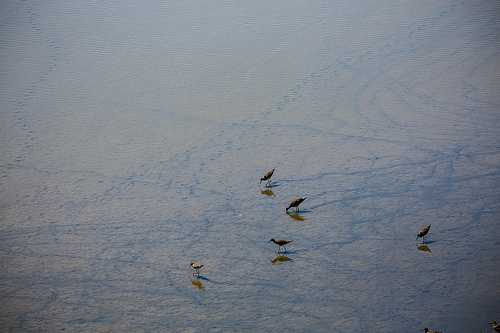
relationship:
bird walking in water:
[259, 168, 276, 186] [16, 102, 468, 301]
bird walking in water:
[284, 194, 319, 216] [16, 102, 468, 301]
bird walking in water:
[414, 224, 432, 241] [16, 102, 468, 301]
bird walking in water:
[256, 230, 306, 270] [16, 102, 468, 301]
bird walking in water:
[414, 224, 432, 241] [9, 1, 479, 321]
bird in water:
[188, 262, 204, 272] [28, 66, 408, 324]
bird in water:
[268, 238, 294, 252] [9, 1, 479, 321]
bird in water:
[414, 224, 432, 241] [9, 1, 479, 321]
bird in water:
[284, 194, 319, 216] [47, 145, 478, 318]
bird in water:
[414, 224, 432, 241] [1, 167, 498, 331]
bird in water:
[256, 169, 283, 186] [9, 1, 479, 321]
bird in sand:
[268, 238, 294, 252] [54, 278, 488, 321]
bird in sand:
[268, 238, 294, 252] [24, 233, 497, 324]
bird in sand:
[414, 224, 432, 241] [7, 245, 496, 333]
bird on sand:
[179, 242, 211, 276] [7, 245, 496, 333]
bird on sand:
[413, 224, 432, 242] [15, 205, 492, 333]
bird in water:
[414, 224, 432, 241] [32, 107, 232, 244]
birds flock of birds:
[187, 168, 432, 277] [173, 154, 434, 293]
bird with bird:
[414, 224, 432, 241] [414, 224, 432, 241]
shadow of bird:
[258, 185, 276, 200] [186, 261, 207, 278]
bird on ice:
[414, 224, 432, 241] [54, 70, 244, 255]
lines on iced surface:
[29, 243, 188, 306] [0, 0, 499, 333]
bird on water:
[188, 262, 204, 272] [9, 1, 479, 321]